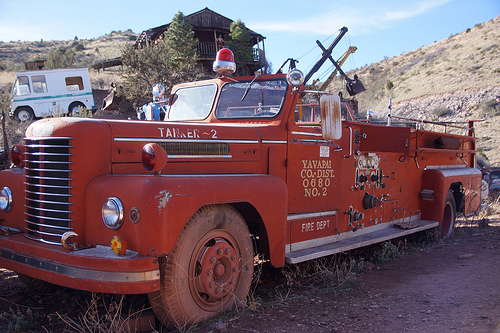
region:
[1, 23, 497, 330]
Red colored recovery truck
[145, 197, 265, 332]
Redish wheel stuck in the ground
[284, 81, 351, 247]
Writings on the door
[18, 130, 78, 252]
Silvery mesh of the radiator area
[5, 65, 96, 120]
White van with a blue strip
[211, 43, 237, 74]
Strobe light with a silver base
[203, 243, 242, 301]
Group of tightened bolts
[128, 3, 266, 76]
Building made of wood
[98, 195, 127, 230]
Round headlight with silver rims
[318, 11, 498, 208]
Gentle hilside without vegetation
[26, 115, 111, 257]
the head of a truck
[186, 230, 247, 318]
the wheel of a truck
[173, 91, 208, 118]
the front screen of a truck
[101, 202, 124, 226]
the front light of a truck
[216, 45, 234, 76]
siren light of a truck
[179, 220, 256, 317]
front wheel of a truck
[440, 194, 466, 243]
back wheel of a truck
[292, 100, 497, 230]
the back of a truck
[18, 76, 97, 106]
a white truck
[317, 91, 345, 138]
side mirror of a truck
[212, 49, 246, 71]
siren on the truck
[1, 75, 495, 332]
old style fire truck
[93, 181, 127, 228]
left headlight on the truck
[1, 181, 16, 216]
right headlight on car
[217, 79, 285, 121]
driver's side windshield on truck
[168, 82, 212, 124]
passenger side windshield on truck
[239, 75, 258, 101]
windshield wipers on window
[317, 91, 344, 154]
rear view mirro on driver's side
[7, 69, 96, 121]
white truck in the background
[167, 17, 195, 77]
tree next to house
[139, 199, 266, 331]
Large reddish colored wheel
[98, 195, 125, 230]
Round large headlight with silver metal frame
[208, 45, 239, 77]
Red strobe light with a silver base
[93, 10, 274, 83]
Wooden structure in the distance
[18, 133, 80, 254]
Meshed metal radiator area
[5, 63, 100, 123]
White van with a blue stripe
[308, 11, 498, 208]
Steep hill side without vegetation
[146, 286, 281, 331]
Wheel section stuck in the ground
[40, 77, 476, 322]
the fire truck is broken dwon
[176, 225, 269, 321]
the tires are brown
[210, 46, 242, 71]
the light is on the truck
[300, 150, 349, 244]
writting is on the door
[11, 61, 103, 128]
the van is white in color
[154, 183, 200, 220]
scratch is on the bumper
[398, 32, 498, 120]
the hill is hilly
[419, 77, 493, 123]
rocks are on the hill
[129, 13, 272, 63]
the house is wooden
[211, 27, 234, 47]
person is in the house